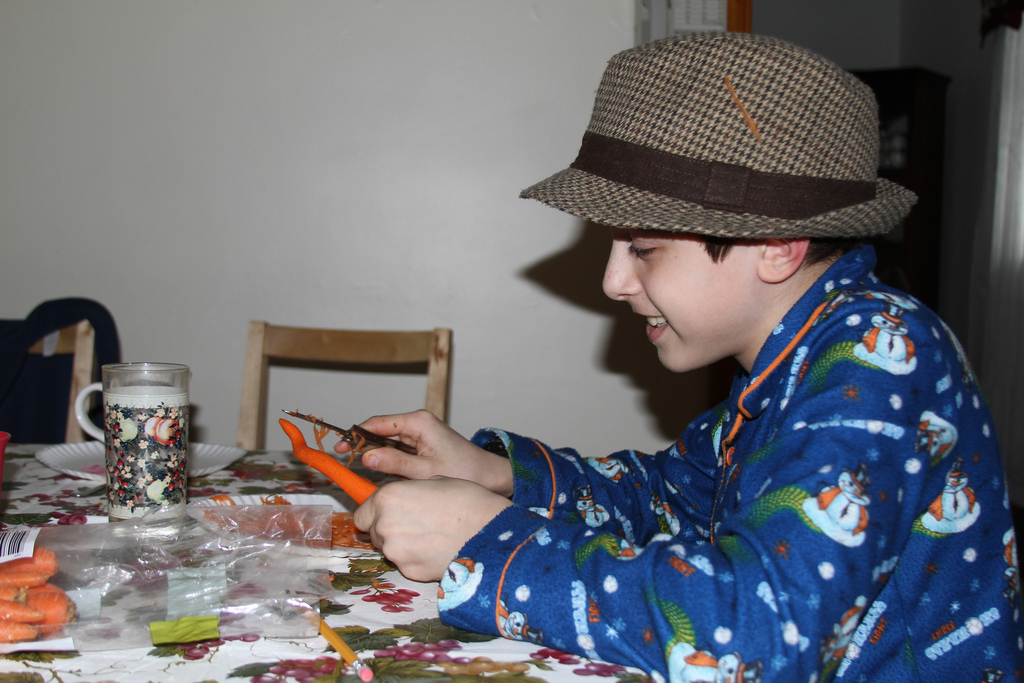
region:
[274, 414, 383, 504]
Orange carrot being peeled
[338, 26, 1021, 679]
Boy in blue pajamas with white snowmen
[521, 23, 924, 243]
Brown houndstooth patterned fedora hat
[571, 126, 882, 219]
Dark brown band on hat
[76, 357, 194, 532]
Tall mug with Christmas pattern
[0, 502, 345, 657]
Clear plastic bag holding carrots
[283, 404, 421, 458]
Paring knife in boy's hand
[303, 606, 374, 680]
Yellow pencil laying on table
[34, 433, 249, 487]
White paper plate on table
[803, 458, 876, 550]
Snowman with top hat and orange vest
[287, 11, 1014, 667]
this is a boy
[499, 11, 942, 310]
a brown fadora hat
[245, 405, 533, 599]
boy holding a carrot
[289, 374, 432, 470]
boy holding a peeler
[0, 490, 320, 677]
a bag of carrots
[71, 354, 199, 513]
glass on the table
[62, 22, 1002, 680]
boy sitting at a table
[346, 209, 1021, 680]
the boy is wearing pajamas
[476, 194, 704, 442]
shadow on the wall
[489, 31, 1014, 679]
a kid sitting at a table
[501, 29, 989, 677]
a kid with a hat on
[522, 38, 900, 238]
a brown and black hat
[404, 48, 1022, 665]
a kid wearing blue pajamas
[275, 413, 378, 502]
a carrot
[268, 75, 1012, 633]
a kid shaving a carrot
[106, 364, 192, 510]
a glass on the table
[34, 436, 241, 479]
a paper plate on the table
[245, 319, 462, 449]
a chair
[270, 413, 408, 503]
orange colored carrot in boys hand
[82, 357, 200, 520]
glass with floral desing filled with milk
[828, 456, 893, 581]
cartoon snow man on boys pjs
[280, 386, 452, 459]
cutting device in boy's right hand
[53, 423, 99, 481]
white paper plate behind glass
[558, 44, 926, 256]
brown plaid hat with brown accents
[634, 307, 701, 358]
toothy smile on the face of a boy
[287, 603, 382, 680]
yellow pencil lying on table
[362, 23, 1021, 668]
boy wearing a checked hat with solid band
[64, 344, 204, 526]
glass with Christmas designs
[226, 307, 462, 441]
wooden chair pulled up to table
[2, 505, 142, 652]
plastic bag filled with carrots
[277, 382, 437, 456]
a metal vegetable peeler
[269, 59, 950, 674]
boy peeling carrots with a vegetable peeler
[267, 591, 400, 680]
yellow pencil laying on table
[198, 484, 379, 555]
carrot peeling in a paper plate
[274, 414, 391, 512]
carrot in a boy's hand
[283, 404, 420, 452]
knife in a boy's hand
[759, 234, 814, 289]
left ear of a boy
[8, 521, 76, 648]
carrots in a bag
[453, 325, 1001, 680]
pajamas on a boy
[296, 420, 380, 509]
carrot in a boy's hand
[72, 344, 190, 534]
a glass of milk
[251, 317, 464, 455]
back of a wooden chair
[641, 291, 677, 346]
teeth of a child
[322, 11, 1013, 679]
boy wearing blue pjs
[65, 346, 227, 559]
christmas mug sitting on table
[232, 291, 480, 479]
brown chair behind table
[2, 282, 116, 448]
jacket hanging on chair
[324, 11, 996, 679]
boy wearing pjs and hat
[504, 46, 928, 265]
boy wearing cloth hat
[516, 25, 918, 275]
boys hat is plaid